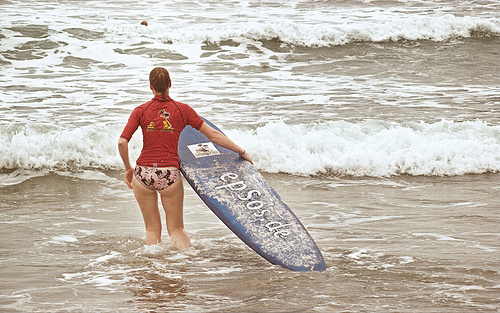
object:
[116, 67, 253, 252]
woman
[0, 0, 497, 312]
ocean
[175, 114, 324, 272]
surfboard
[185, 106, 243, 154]
arm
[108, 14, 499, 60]
wave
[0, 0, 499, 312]
foam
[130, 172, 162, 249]
leg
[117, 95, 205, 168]
shirt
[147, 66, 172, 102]
hair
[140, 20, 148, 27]
head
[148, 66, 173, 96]
head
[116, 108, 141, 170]
arm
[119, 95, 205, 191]
suit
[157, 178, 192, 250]
leg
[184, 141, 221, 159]
logo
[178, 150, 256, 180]
sand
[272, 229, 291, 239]
letters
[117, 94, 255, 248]
body